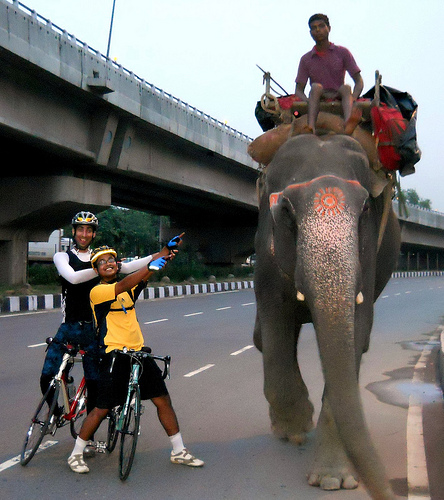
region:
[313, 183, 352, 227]
small circular orange patterned disk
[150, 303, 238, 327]
portion of white broken line on road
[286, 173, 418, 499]
large gray elephant tusk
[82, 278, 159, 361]
man's black and orange biking shirt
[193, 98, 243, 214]
portion of highway overpass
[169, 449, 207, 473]
man's gray and white sneakers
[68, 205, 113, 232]
multi colored bike helmet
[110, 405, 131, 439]
dark green water bottle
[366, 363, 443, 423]
large water spot on street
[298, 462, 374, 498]
elephant toes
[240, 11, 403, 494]
A man on elephant.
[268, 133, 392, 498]
Elephant's painted head.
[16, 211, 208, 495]
Boys on bicycles.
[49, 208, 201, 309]
Boys pointing at elephant.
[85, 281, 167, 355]
Boy wearing yellow shirt.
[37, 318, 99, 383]
Boy wearing blue pants.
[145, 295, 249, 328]
White dividers in road.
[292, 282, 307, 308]
Part of an elephant's tusk.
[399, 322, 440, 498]
Line at edge of road.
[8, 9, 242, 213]
Overpass above the road.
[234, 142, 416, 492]
a tall grey elephant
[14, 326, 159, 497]
two bicycles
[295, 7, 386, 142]
a person on an elephant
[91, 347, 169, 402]
a pair of black shorts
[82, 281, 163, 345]
a person's bright yellow shirt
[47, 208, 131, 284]
two people's smiling faces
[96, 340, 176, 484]
a light blue bicycle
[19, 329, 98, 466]
a red bicycle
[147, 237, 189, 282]
blue cycling gloves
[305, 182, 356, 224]
orange marking on an elephant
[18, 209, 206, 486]
two men on bikes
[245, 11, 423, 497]
a man on an elephant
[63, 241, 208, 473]
a man wearing a yellow shirt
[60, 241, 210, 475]
a man wearing a helmet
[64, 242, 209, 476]
a man wearing shorts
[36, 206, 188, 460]
a man wearing a black and white shirt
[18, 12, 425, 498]
two men pointing at a man on an elephant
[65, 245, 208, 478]
a man wearing white shoes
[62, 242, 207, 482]
a man wearing blue gloves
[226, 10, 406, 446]
man riding on a elephant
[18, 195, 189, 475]
two boys on bikes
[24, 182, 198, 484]
two boys pointing to the right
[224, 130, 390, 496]
a grey elephant with paint on face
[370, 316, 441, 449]
water puddles on the road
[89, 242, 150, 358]
young boy wearing a yellow shirt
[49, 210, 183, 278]
tall boy wearing a long sleeve white shirt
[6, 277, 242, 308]
black and white striped curb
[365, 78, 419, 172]
a red back pack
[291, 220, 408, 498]
a really long elephant trunk